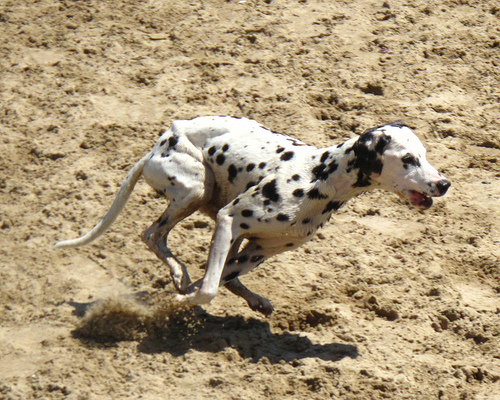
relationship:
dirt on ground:
[0, 0, 500, 400] [0, 0, 498, 399]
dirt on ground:
[1, 3, 498, 395] [0, 0, 498, 399]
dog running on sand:
[54, 114, 452, 317] [2, 0, 499, 397]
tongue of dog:
[409, 187, 424, 207] [52, 121, 448, 309]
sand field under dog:
[2, 251, 497, 398] [52, 121, 448, 309]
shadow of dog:
[70, 298, 356, 360] [77, 99, 489, 296]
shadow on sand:
[70, 298, 356, 360] [2, 0, 499, 397]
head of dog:
[357, 122, 450, 211] [116, 73, 463, 335]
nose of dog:
[437, 179, 451, 192] [54, 114, 452, 317]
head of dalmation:
[357, 122, 450, 211] [51, 111, 451, 318]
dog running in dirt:
[54, 114, 452, 317] [1, 3, 498, 395]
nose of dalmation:
[437, 179, 447, 192] [51, 111, 451, 318]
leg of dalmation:
[158, 178, 290, 305] [51, 111, 451, 318]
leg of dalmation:
[138, 154, 214, 298] [51, 111, 451, 318]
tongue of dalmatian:
[409, 187, 424, 207] [16, 73, 457, 333]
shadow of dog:
[114, 257, 356, 360] [171, 103, 472, 333]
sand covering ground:
[2, 0, 499, 397] [0, 0, 498, 399]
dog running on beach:
[54, 114, 452, 317] [0, 1, 499, 398]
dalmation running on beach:
[51, 111, 451, 318] [0, 1, 499, 398]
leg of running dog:
[138, 154, 214, 271] [54, 114, 452, 317]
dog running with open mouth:
[91, 105, 471, 317] [401, 169, 457, 216]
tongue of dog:
[405, 187, 424, 210] [57, 84, 465, 340]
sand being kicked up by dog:
[0, 0, 498, 400] [2, 94, 435, 364]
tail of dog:
[53, 148, 153, 248] [54, 114, 452, 317]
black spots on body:
[225, 144, 302, 208] [128, 110, 382, 262]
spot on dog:
[158, 138, 169, 148] [54, 114, 452, 317]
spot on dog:
[278, 150, 293, 160] [54, 114, 452, 317]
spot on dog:
[238, 222, 250, 229] [54, 114, 452, 317]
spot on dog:
[283, 240, 294, 247] [54, 114, 452, 317]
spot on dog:
[207, 145, 215, 155] [54, 114, 452, 317]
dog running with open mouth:
[54, 114, 452, 317] [404, 183, 440, 208]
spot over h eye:
[393, 148, 418, 171] [398, 152, 420, 164]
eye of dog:
[398, 152, 420, 164] [54, 114, 452, 317]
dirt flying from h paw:
[0, 0, 500, 400] [171, 277, 193, 292]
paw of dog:
[171, 277, 193, 292] [202, 109, 423, 212]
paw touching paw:
[161, 290, 208, 326] [161, 261, 195, 290]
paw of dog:
[161, 290, 208, 326] [52, 121, 448, 309]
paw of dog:
[161, 261, 195, 290] [52, 121, 448, 309]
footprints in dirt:
[41, 1, 484, 382] [1, 3, 498, 395]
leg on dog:
[181, 178, 289, 305] [54, 114, 452, 317]